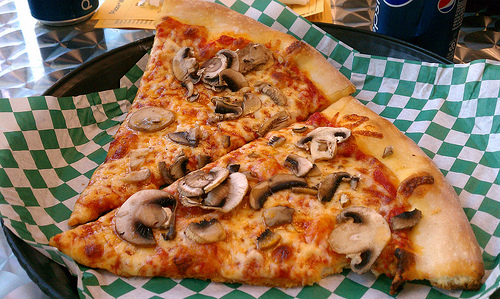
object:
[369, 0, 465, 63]
soda can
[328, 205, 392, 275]
mushroom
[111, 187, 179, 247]
mushroom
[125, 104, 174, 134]
mushroom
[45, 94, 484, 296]
pizza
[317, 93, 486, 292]
crust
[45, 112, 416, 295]
cheese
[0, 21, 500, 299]
black plate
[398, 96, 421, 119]
green white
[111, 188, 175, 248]
mushroom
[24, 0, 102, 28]
bottom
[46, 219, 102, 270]
tips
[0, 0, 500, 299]
paper